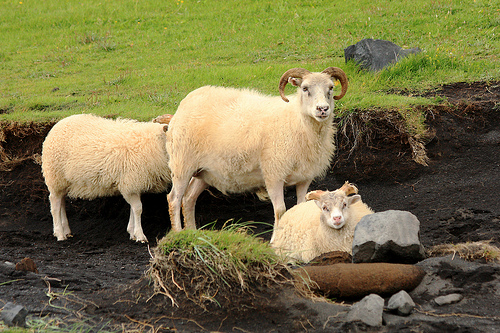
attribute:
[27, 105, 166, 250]
sheep — standing, white, wooly, green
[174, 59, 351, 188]
sheep — standing, white, wooly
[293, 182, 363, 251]
sheep — white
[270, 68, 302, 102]
horn — brown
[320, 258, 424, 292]
log — brown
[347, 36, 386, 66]
rock — gray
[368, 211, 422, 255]
rock — gray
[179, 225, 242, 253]
grass — long, green, brown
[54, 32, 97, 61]
grass — short, green, yellow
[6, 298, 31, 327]
rock — gray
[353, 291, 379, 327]
rock — gray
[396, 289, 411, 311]
rock — gray